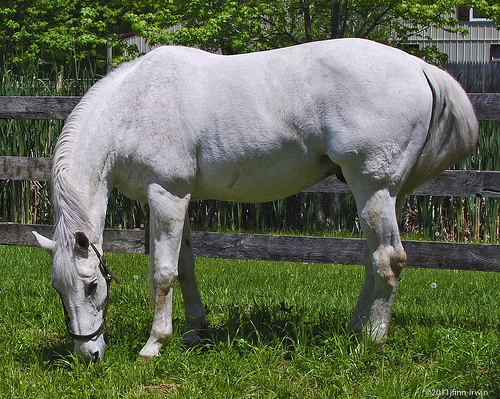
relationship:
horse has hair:
[46, 20, 482, 346] [64, 101, 89, 236]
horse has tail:
[46, 20, 482, 346] [392, 56, 479, 219]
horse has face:
[46, 20, 482, 346] [50, 240, 109, 339]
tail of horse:
[392, 56, 479, 219] [46, 20, 482, 346]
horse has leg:
[46, 20, 482, 346] [334, 168, 432, 355]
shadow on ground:
[182, 305, 308, 348] [5, 235, 450, 361]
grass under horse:
[20, 329, 171, 389] [46, 20, 482, 346]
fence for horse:
[14, 87, 52, 301] [46, 20, 482, 346]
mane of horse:
[45, 52, 143, 182] [46, 20, 482, 346]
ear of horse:
[60, 218, 127, 282] [46, 20, 482, 346]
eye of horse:
[69, 278, 118, 300] [46, 20, 482, 346]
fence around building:
[14, 87, 52, 301] [377, 4, 499, 93]